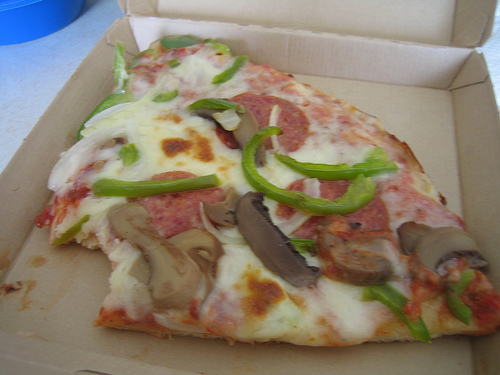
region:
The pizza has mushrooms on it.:
[403, 210, 480, 288]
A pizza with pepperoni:
[236, 91, 339, 163]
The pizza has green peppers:
[240, 108, 419, 219]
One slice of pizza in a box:
[107, 39, 447, 369]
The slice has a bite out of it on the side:
[37, 204, 234, 339]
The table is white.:
[12, 36, 127, 111]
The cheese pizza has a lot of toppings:
[100, 50, 498, 327]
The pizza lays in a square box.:
[32, 29, 497, 325]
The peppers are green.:
[226, 116, 408, 211]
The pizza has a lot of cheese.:
[78, 67, 298, 208]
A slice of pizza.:
[30, 25, 498, 362]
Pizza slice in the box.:
[5, 5, 496, 367]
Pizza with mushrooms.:
[94, 62, 493, 359]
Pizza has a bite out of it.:
[38, 30, 490, 360]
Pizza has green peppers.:
[48, 22, 492, 359]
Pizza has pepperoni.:
[42, 22, 494, 360]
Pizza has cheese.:
[42, 22, 498, 369]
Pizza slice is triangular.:
[41, 17, 491, 365]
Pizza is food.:
[39, 27, 490, 364]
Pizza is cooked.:
[32, 27, 494, 359]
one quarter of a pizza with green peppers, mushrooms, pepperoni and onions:
[1, 0, 497, 371]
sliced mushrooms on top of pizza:
[235, 186, 320, 283]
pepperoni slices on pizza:
[140, 175, 221, 237]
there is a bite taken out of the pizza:
[43, 190, 175, 337]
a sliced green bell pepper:
[243, 124, 372, 209]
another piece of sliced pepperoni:
[217, 88, 309, 153]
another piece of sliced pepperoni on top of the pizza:
[278, 171, 389, 239]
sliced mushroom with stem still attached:
[106, 195, 223, 300]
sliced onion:
[45, 102, 151, 189]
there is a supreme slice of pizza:
[158, 32, 468, 340]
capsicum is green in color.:
[249, 136, 351, 206]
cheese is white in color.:
[289, 284, 374, 324]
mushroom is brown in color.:
[116, 210, 216, 295]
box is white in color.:
[24, 308, 74, 345]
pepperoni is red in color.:
[133, 196, 206, 232]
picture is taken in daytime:
[13, 87, 291, 259]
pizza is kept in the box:
[43, 58, 383, 315]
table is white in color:
[6, 52, 52, 118]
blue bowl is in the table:
[1, 15, 83, 55]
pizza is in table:
[32, 68, 223, 207]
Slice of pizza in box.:
[44, 28, 494, 344]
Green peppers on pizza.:
[242, 144, 397, 211]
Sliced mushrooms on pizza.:
[105, 201, 229, 310]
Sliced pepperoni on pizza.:
[238, 89, 316, 147]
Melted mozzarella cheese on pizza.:
[83, 121, 153, 173]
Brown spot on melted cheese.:
[233, 264, 289, 322]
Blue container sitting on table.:
[3, 6, 85, 43]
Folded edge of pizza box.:
[0, 13, 133, 270]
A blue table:
[8, 48, 41, 117]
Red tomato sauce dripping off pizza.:
[31, 183, 89, 236]